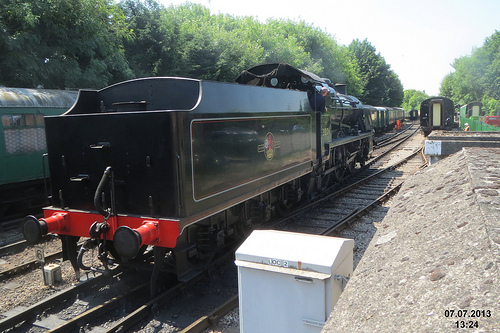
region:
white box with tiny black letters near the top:
[227, 214, 372, 331]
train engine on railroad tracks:
[36, 63, 387, 287]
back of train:
[415, 88, 462, 143]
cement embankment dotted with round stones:
[400, 166, 482, 232]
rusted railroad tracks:
[31, 285, 167, 330]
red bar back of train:
[27, 200, 187, 264]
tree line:
[263, 9, 396, 81]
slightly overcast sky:
[386, 12, 450, 72]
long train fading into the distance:
[370, 102, 414, 130]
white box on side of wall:
[422, 136, 449, 156]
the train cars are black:
[1, 25, 481, 302]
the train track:
[18, 290, 210, 326]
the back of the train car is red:
[25, 194, 187, 304]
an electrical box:
[231, 208, 363, 329]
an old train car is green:
[6, 77, 57, 204]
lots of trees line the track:
[110, 7, 295, 72]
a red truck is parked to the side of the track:
[476, 108, 499, 137]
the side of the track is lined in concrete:
[388, 177, 482, 299]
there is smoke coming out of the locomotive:
[298, 17, 352, 88]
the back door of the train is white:
[411, 72, 459, 148]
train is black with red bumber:
[12, 49, 414, 265]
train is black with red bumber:
[48, 87, 243, 232]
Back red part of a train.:
[43, 205, 179, 248]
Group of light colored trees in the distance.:
[400, 89, 430, 118]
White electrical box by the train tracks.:
[235, 226, 353, 331]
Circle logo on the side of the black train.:
[254, 128, 284, 162]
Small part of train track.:
[0, 222, 95, 276]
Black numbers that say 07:
[443, 307, 455, 317]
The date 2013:
[470, 309, 494, 317]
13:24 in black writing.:
[455, 320, 479, 330]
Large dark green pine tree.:
[345, 35, 391, 107]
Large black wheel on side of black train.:
[332, 143, 348, 180]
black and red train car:
[41, 71, 336, 263]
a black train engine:
[258, 53, 415, 201]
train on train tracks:
[36, 63, 411, 271]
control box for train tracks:
[217, 220, 380, 332]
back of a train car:
[412, 83, 462, 146]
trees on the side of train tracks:
[299, 30, 411, 125]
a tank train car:
[1, 78, 43, 253]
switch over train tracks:
[384, 120, 421, 170]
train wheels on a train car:
[180, 211, 237, 294]